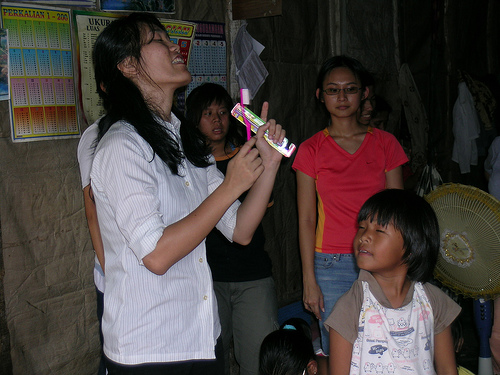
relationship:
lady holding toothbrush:
[90, 12, 286, 373] [240, 88, 252, 141]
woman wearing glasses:
[292, 56, 410, 355] [323, 86, 363, 94]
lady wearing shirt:
[184, 82, 281, 374] [206, 147, 276, 283]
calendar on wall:
[1, 2, 83, 144] [1, 0, 494, 371]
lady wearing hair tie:
[259, 317, 320, 373] [284, 323, 296, 329]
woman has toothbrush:
[90, 12, 286, 373] [240, 88, 252, 141]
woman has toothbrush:
[90, 12, 286, 373] [231, 102, 297, 158]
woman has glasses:
[292, 56, 410, 355] [323, 86, 363, 94]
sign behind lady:
[72, 9, 132, 131] [90, 12, 286, 373]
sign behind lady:
[154, 16, 195, 118] [90, 12, 286, 373]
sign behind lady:
[184, 20, 226, 102] [90, 12, 286, 373]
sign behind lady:
[1, 29, 13, 101] [90, 12, 286, 373]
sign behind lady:
[99, 0, 177, 15] [90, 12, 286, 373]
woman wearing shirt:
[292, 56, 410, 355] [291, 126, 409, 255]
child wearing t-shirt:
[323, 188, 464, 374] [323, 269, 464, 373]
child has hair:
[323, 188, 464, 374] [357, 188, 440, 283]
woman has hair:
[292, 56, 410, 355] [316, 56, 366, 92]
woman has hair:
[90, 12, 286, 373] [88, 13, 214, 176]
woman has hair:
[184, 82, 281, 374] [184, 83, 248, 153]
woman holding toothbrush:
[90, 12, 286, 373] [240, 88, 252, 141]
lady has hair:
[90, 12, 286, 373] [88, 13, 214, 176]